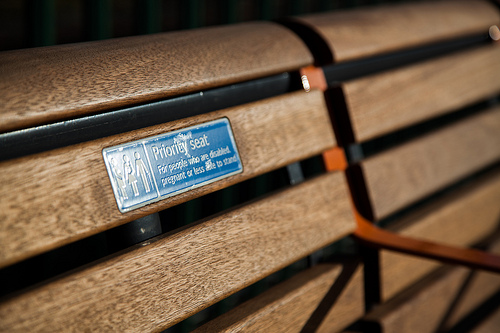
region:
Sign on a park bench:
[95, 113, 252, 205]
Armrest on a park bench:
[352, 194, 497, 282]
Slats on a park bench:
[37, 73, 355, 306]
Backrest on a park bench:
[38, 50, 328, 316]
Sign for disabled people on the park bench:
[97, 108, 261, 218]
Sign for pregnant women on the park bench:
[102, 116, 247, 210]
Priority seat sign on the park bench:
[79, 108, 249, 220]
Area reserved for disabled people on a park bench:
[24, 26, 345, 331]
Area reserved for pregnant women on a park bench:
[6, 39, 366, 331]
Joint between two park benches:
[290, 24, 431, 331]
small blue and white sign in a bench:
[98, 112, 246, 218]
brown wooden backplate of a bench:
[0, 9, 493, 329]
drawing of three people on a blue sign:
[104, 137, 153, 207]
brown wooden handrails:
[316, 90, 499, 284]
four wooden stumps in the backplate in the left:
[1, 17, 365, 325]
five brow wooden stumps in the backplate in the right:
[320, 0, 491, 332]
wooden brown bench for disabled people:
[4, 18, 496, 327]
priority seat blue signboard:
[104, 113, 242, 221]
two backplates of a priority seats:
[7, 11, 494, 332]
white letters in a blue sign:
[151, 119, 237, 196]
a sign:
[85, 75, 253, 285]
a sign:
[104, 157, 231, 301]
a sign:
[191, 182, 282, 330]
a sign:
[167, 146, 248, 323]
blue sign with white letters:
[96, 134, 252, 220]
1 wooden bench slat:
[221, 227, 324, 280]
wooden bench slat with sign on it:
[44, 162, 69, 225]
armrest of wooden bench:
[378, 221, 469, 287]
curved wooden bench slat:
[83, 52, 102, 59]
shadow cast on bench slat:
[280, 285, 380, 322]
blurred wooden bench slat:
[343, 79, 432, 122]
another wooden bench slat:
[432, 222, 490, 270]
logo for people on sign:
[101, 150, 158, 202]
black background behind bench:
[25, 126, 78, 153]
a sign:
[177, 148, 329, 308]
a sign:
[132, 64, 332, 276]